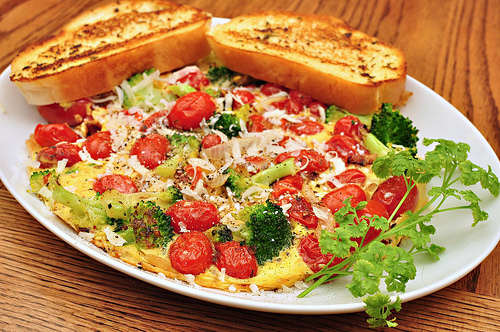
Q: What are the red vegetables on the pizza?
A: Tomatoes.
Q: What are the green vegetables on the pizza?
A: Broccoli.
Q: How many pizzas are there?
A: One.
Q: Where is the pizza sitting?
A: On a plate.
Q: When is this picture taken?
A: Lunch time.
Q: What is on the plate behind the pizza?
A: Garlic bread.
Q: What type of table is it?
A: Wood.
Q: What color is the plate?
A: White.